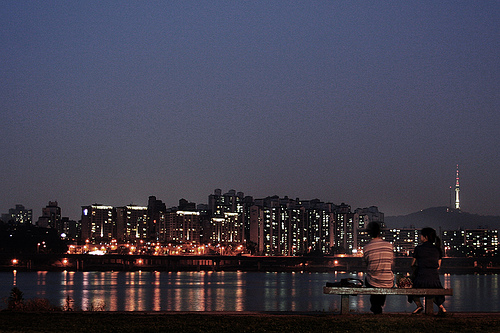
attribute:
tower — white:
[431, 170, 496, 238]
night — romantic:
[7, 1, 497, 325]